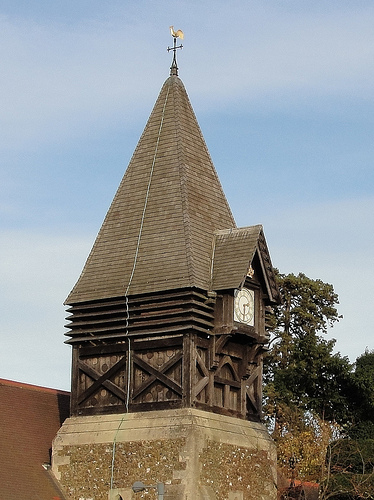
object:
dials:
[244, 304, 252, 307]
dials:
[241, 304, 245, 320]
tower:
[164, 26, 188, 81]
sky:
[6, 9, 372, 368]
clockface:
[235, 286, 255, 325]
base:
[48, 402, 280, 499]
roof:
[62, 76, 282, 303]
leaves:
[266, 395, 361, 491]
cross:
[164, 26, 185, 67]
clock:
[233, 286, 254, 326]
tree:
[268, 268, 339, 338]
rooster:
[167, 21, 185, 49]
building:
[49, 26, 280, 498]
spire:
[49, 35, 285, 495]